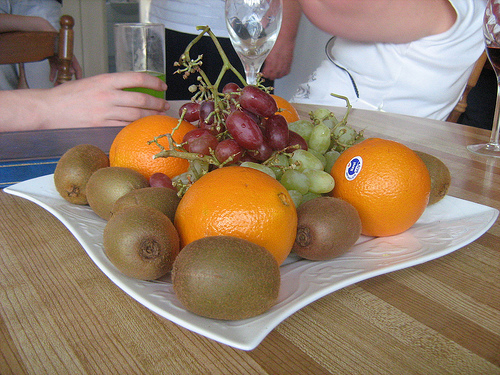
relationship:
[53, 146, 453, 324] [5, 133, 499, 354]
kiwi on plate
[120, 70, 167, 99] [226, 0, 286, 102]
liquid in glass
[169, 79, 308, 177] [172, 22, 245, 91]
grape with stem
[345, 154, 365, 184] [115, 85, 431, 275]
tag on orange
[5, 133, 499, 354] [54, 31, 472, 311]
plate full fruits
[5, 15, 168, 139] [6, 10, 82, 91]
arm on chair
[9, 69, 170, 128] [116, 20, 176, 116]
hand on glass